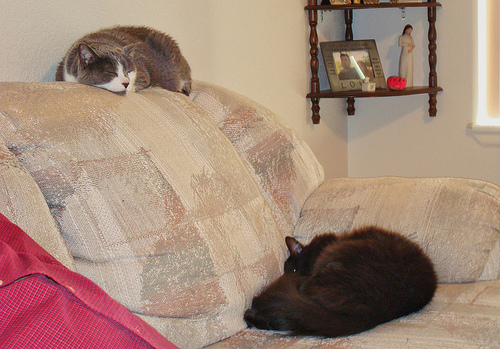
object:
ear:
[285, 236, 305, 255]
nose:
[121, 82, 131, 88]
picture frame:
[318, 38, 391, 94]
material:
[0, 212, 175, 348]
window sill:
[462, 114, 499, 149]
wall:
[2, 1, 499, 191]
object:
[387, 75, 407, 91]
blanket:
[0, 215, 185, 349]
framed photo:
[331, 49, 375, 80]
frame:
[320, 39, 387, 93]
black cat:
[246, 225, 438, 340]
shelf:
[301, 0, 444, 125]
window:
[472, 1, 500, 137]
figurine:
[398, 24, 417, 87]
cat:
[54, 24, 190, 97]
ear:
[122, 41, 141, 58]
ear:
[77, 41, 101, 70]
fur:
[121, 26, 171, 63]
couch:
[2, 81, 500, 348]